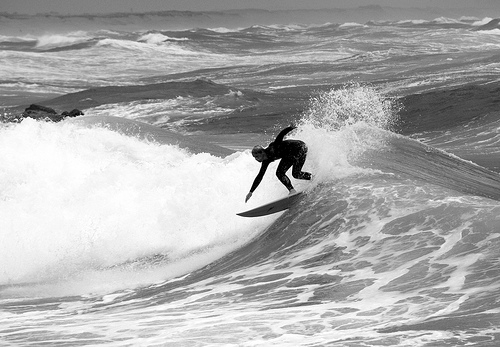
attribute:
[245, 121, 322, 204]
man — dark, standing, surfing, wet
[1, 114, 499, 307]
wave — white, large, crashing, gray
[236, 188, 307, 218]
surfboard — gray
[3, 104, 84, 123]
rocks — brown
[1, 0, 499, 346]
water — grey, ocean water, foamy, white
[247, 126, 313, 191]
wetsuit — black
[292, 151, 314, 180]
leg — back leg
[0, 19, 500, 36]
beach — gray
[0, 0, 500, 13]
sky — cloudy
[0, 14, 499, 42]
waves — gray